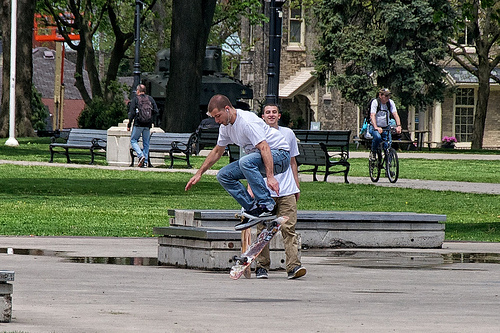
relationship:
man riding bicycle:
[355, 81, 412, 186] [361, 122, 406, 187]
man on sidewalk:
[355, 81, 412, 186] [1, 154, 500, 202]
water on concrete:
[1, 240, 192, 274] [1, 228, 499, 331]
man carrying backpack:
[123, 81, 154, 174] [135, 92, 155, 127]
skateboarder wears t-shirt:
[178, 93, 301, 231] [212, 105, 293, 158]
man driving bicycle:
[355, 81, 412, 186] [361, 122, 406, 187]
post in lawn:
[3, 1, 23, 152] [3, 123, 499, 244]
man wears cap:
[355, 81, 412, 186] [375, 84, 395, 99]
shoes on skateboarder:
[241, 199, 278, 226] [178, 93, 301, 231]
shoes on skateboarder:
[243, 204, 277, 220] [178, 93, 301, 231]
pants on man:
[239, 185, 308, 275] [245, 98, 311, 282]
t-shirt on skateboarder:
[212, 105, 293, 158] [178, 93, 301, 231]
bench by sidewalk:
[43, 118, 120, 165] [1, 154, 500, 202]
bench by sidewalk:
[127, 123, 197, 173] [1, 154, 500, 202]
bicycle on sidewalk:
[361, 122, 406, 187] [1, 154, 500, 202]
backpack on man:
[135, 92, 155, 127] [123, 81, 154, 174]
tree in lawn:
[1, 0, 46, 148] [3, 123, 499, 244]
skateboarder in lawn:
[178, 93, 301, 231] [3, 123, 499, 244]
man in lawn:
[245, 98, 311, 282] [3, 123, 499, 244]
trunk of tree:
[156, 2, 218, 137] [156, 1, 224, 120]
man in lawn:
[355, 81, 412, 186] [3, 123, 499, 244]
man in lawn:
[123, 81, 154, 174] [3, 123, 499, 244]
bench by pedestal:
[43, 118, 120, 165] [103, 116, 175, 170]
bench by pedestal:
[127, 123, 197, 173] [103, 116, 175, 170]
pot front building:
[440, 133, 460, 150] [235, 0, 499, 162]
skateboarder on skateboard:
[178, 93, 301, 231] [223, 209, 294, 282]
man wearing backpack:
[123, 81, 154, 174] [135, 92, 155, 127]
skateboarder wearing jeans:
[178, 93, 301, 231] [213, 144, 299, 218]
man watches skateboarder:
[245, 98, 311, 282] [178, 93, 301, 231]